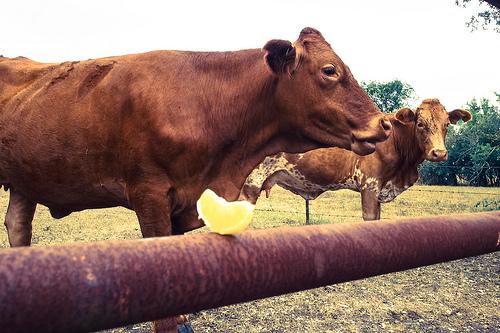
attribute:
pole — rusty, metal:
[1, 209, 500, 332]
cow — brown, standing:
[1, 28, 394, 249]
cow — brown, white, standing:
[237, 98, 472, 229]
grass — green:
[1, 184, 500, 331]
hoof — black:
[175, 321, 194, 332]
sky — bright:
[1, 0, 500, 132]